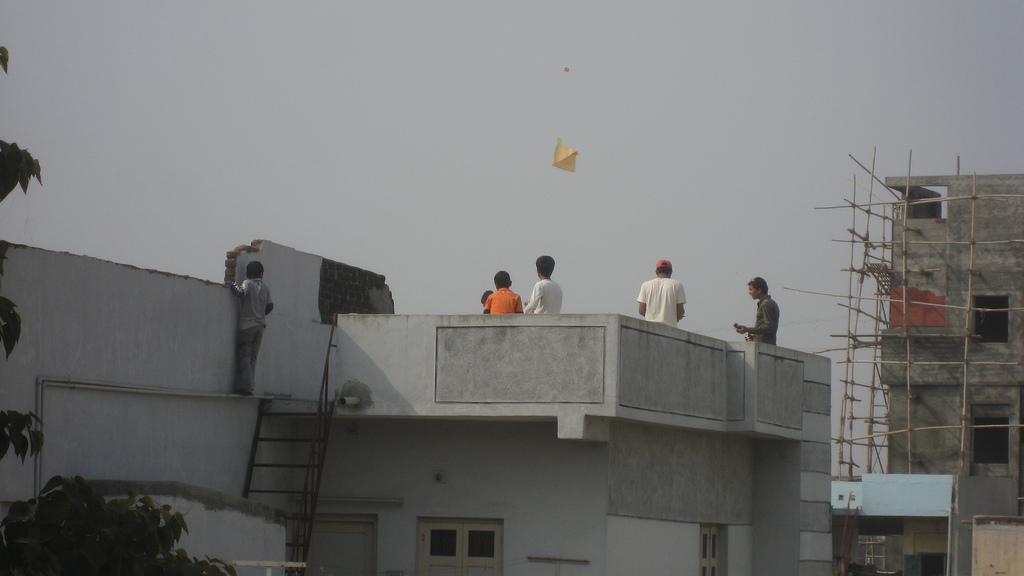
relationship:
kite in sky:
[540, 133, 589, 176] [477, 93, 706, 253]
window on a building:
[894, 178, 955, 226] [877, 178, 1023, 466]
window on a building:
[461, 522, 504, 554] [331, 276, 740, 568]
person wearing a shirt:
[485, 272, 524, 310] [485, 272, 524, 310]